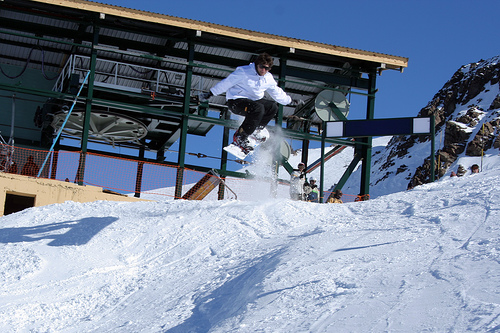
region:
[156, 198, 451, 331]
markings in the snow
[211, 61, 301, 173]
person in the air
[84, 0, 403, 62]
roof over the covering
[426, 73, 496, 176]
rocks in the snow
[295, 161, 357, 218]
people on the hill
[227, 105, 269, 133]
dark pants on the skier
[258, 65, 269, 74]
goggles on the face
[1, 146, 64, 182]
figures in the back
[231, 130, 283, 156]
board is white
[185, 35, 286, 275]
A person is in the air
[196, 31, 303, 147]
A person is wearing a white jacket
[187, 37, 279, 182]
A person is using a snowboard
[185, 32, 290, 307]
The person is doing some snowboarding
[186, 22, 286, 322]
A person is having great fun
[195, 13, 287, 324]
The person is enjoying some recreation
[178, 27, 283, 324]
The person is out in the daytime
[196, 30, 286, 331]
The person is enjoying their day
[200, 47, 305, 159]
A snowboarder doing a jump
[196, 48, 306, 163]
A snowboarder doing a jump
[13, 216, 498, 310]
The snow is white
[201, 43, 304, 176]
The person is on a snowboard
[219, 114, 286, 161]
The snowboard is white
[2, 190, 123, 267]
The shadow is of the snowboarder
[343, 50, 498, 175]
There is a mountain in the background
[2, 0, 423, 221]
There is a building in the background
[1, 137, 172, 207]
There are people standing on the platform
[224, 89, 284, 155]
The snowboarder's pants are black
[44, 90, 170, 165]
There is a large silver circle on the roof of the building.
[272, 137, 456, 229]
There are people in the background.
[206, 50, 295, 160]
Person jumping on snowboard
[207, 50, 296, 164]
Person on white snowboard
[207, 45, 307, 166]
Snowboarder doing a jump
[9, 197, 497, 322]
Snow covered hill for skiing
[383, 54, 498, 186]
Rocky snow covered mountain top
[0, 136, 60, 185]
People in the background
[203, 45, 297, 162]
Person wearing white ski jacket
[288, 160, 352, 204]
People in the background watching the snowboarder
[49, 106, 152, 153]
Large mechanical wheel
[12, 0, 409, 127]
Large metal roof